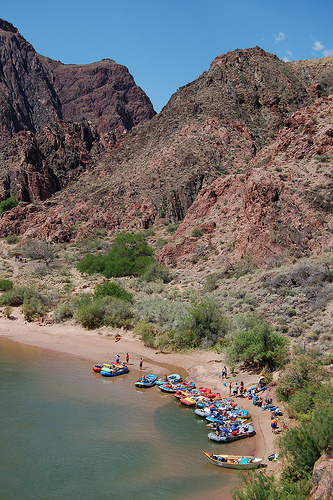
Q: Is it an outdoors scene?
A: Yes, it is outdoors.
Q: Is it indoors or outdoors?
A: It is outdoors.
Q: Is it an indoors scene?
A: No, it is outdoors.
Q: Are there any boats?
A: Yes, there is a boat.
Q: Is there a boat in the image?
A: Yes, there is a boat.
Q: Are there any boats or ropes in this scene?
A: Yes, there is a boat.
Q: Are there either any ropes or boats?
A: Yes, there is a boat.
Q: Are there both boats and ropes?
A: No, there is a boat but no ropes.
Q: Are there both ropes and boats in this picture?
A: No, there is a boat but no ropes.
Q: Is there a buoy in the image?
A: No, there are no buoys.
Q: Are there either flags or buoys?
A: No, there are no buoys or flags.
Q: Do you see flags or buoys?
A: No, there are no buoys or flags.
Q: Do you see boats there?
A: Yes, there is a boat.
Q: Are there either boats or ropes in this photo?
A: Yes, there is a boat.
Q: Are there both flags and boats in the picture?
A: No, there is a boat but no flags.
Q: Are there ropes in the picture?
A: No, there are no ropes.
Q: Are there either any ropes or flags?
A: No, there are no ropes or flags.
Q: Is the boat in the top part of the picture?
A: No, the boat is in the bottom of the image.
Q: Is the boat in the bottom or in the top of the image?
A: The boat is in the bottom of the image.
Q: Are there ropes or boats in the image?
A: Yes, there is a boat.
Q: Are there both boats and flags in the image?
A: No, there is a boat but no flags.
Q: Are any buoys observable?
A: No, there are no buoys.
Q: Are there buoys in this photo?
A: No, there are no buoys.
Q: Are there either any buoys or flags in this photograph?
A: No, there are no buoys or flags.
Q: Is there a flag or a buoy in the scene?
A: No, there are no buoys or flags.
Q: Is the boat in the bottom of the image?
A: Yes, the boat is in the bottom of the image.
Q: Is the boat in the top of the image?
A: No, the boat is in the bottom of the image.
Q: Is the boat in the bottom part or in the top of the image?
A: The boat is in the bottom of the image.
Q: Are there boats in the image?
A: Yes, there is a boat.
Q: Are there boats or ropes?
A: Yes, there is a boat.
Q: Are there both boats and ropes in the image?
A: No, there is a boat but no ropes.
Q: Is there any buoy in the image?
A: No, there are no buoys.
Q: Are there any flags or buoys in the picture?
A: No, there are no buoys or flags.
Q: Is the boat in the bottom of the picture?
A: Yes, the boat is in the bottom of the image.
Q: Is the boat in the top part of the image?
A: No, the boat is in the bottom of the image.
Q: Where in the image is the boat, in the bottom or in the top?
A: The boat is in the bottom of the image.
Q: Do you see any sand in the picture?
A: Yes, there is sand.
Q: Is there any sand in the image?
A: Yes, there is sand.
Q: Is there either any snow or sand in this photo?
A: Yes, there is sand.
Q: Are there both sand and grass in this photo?
A: Yes, there are both sand and grass.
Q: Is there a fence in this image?
A: No, there are no fences.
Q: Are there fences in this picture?
A: No, there are no fences.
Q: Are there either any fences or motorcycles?
A: No, there are no fences or motorcycles.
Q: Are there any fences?
A: No, there are no fences.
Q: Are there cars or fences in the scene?
A: No, there are no fences or cars.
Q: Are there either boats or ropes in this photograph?
A: Yes, there is a boat.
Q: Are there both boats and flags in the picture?
A: No, there is a boat but no flags.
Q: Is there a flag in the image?
A: No, there are no flags.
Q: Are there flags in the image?
A: No, there are no flags.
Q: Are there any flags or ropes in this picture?
A: No, there are no flags or ropes.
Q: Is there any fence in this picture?
A: No, there are no fences.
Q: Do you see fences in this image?
A: No, there are no fences.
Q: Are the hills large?
A: Yes, the hills are large.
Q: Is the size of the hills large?
A: Yes, the hills are large.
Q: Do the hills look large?
A: Yes, the hills are large.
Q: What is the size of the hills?
A: The hills are large.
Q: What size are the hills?
A: The hills are large.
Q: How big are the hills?
A: The hills are large.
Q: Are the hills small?
A: No, the hills are large.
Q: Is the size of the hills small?
A: No, the hills are large.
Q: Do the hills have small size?
A: No, the hills are large.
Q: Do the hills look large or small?
A: The hills are large.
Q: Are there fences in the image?
A: No, there are no fences.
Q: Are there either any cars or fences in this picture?
A: No, there are no fences or cars.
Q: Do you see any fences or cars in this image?
A: No, there are no fences or cars.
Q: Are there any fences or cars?
A: No, there are no fences or cars.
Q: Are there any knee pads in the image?
A: No, there are no knee pads.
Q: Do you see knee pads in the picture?
A: No, there are no knee pads.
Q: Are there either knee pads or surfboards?
A: No, there are no knee pads or surfboards.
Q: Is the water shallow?
A: Yes, the water is shallow.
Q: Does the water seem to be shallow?
A: Yes, the water is shallow.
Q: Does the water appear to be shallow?
A: Yes, the water is shallow.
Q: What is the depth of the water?
A: The water is shallow.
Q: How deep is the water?
A: The water is shallow.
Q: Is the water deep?
A: No, the water is shallow.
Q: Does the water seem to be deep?
A: No, the water is shallow.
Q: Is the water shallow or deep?
A: The water is shallow.